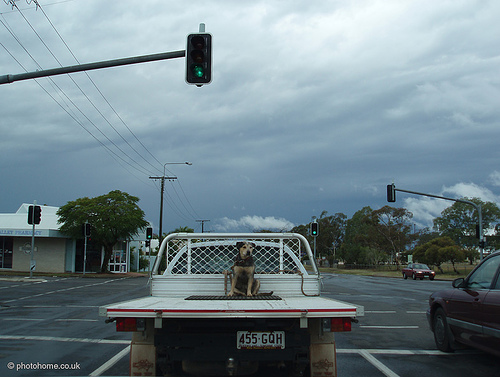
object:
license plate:
[237, 330, 286, 350]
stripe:
[334, 349, 440, 356]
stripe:
[0, 335, 131, 346]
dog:
[226, 242, 273, 298]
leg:
[227, 268, 239, 296]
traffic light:
[386, 183, 396, 202]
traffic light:
[145, 228, 153, 240]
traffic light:
[310, 221, 320, 237]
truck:
[97, 232, 366, 377]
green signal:
[194, 64, 204, 77]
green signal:
[147, 235, 151, 239]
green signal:
[312, 231, 316, 235]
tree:
[54, 189, 150, 276]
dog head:
[236, 241, 257, 257]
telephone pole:
[159, 177, 166, 248]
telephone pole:
[201, 221, 203, 234]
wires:
[167, 180, 201, 224]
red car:
[402, 263, 436, 281]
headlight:
[431, 271, 436, 274]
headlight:
[415, 270, 423, 274]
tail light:
[330, 318, 352, 332]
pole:
[0, 50, 186, 87]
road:
[5, 274, 498, 375]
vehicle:
[426, 249, 498, 366]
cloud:
[207, 215, 292, 235]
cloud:
[402, 181, 499, 234]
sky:
[0, 0, 500, 203]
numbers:
[239, 333, 245, 343]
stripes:
[358, 325, 420, 329]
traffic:
[0, 231, 500, 377]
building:
[0, 202, 148, 277]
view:
[6, 217, 484, 297]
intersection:
[3, 166, 500, 375]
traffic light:
[186, 33, 211, 84]